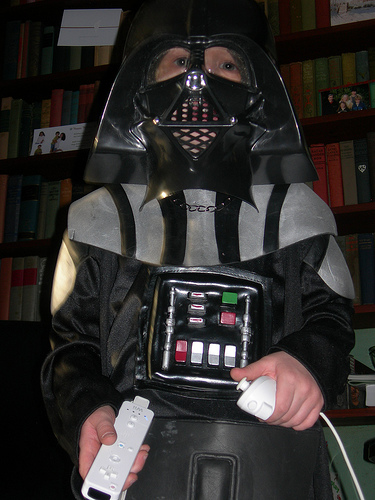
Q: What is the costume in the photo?
A: Dark vader.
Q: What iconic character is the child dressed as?
A: Darth Vader.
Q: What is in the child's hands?
A: Game controls.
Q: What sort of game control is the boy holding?
A: A Wii.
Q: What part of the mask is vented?
A: The area across the mouth and chin.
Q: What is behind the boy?
A: Bookshelves.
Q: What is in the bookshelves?
A: Many books.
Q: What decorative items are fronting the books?
A: Photos.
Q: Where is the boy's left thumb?
A: On the push button, of the control device, in his left hand.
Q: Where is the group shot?
A: On a book shelf, to the right of the boy, directly across the helmet.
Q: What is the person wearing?
A: A Darth Vader costume.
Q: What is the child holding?
A: A Wii controller.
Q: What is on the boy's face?
A: A mask.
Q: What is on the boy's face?
A: A mask.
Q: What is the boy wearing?
A: A costume.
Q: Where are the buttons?
A: On the front of the costume.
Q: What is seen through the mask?
A: The eyes.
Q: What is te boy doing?
A: Playing a game.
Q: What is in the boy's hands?
A: Remotes.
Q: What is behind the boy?
A: Books on a shelf.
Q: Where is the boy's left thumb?
A: On the button.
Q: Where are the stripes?
A: Below the boy's neck on the costume.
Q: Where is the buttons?
A: Below the neck.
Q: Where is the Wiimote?
A: In the boys hands.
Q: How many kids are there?
A: One.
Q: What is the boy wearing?
A: A Darth Vader costume.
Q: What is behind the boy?
A: Books.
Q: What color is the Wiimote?
A: White.